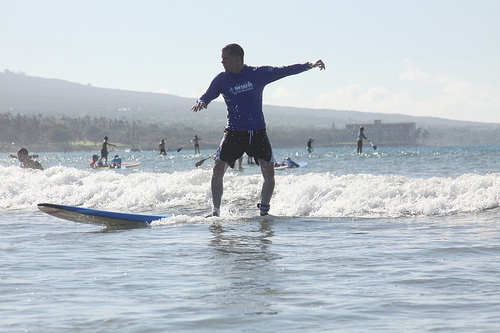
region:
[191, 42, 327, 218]
a man standing on a surfboard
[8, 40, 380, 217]
people playing in the water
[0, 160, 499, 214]
gentle waves in the water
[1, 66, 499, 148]
a hill behind the water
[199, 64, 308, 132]
a blue shirt on the man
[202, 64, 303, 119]
Blue shirt on a man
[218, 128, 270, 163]
Black shorts on a man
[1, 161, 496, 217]
Wave splashing toward a man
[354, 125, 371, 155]
Person in the water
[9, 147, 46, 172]
Person in the water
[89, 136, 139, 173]
People playing in the water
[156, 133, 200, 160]
People in the water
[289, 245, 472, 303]
Ripples in the water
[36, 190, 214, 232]
The blue surfboard is in the water.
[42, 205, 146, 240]
The bottom of the surfboard is white.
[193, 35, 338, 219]
The person is on top of the surfboard.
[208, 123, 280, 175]
The man is wearing a black pant.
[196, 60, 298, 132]
The man is wearing a blue shirt.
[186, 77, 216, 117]
The left arm of the man .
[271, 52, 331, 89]
The right arm of the man.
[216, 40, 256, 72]
The head of the man.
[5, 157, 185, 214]
The white foam on the wave.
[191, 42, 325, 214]
A man with short hair surfing.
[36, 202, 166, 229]
A white and blue surfboard.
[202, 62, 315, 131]
Blue long sleeve shirt on a man surfing.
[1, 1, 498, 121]
A white and blue sky.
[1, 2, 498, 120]
Light blue sky with clouds.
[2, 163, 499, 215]
A small white wave.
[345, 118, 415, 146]
Very large building in the distance.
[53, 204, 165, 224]
Blue edge of a surfboard.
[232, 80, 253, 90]
White mwh on a man's blue shirt front.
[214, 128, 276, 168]
Black and white shorts on a man surfing.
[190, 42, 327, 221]
man on a surfboard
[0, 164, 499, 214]
gentle waves in the water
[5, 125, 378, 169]
people in the background playing in the water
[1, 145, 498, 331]
a large body of water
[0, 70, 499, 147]
green hills behind the water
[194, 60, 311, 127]
blue shirt on the man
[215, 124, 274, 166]
black shorts on the man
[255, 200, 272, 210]
anklet on the man's ankle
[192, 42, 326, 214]
Man in the water surfing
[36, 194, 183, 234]
Long blue surfboard in water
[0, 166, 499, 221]
Large white crashing wave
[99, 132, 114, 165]
Short kid on surfboard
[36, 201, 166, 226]
A blue surfboard coming out of the water.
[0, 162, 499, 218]
A white wave rolling into the shore.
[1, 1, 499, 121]
A blue sky with white clouds.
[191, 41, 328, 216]
A man standing up on a surfboard in a blue shirt and black shorts.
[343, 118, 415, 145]
A large building past the water.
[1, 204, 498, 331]
A blue rippled body of water ahead of the wave.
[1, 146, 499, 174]
A blue body of water behind the wave.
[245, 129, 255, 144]
White tie strings on a black pair of shorts.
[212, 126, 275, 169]
Black and white pair of shorts.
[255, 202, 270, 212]
Black and white ankle strap for a surfboard on a mans left ankle.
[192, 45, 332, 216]
a person is standing up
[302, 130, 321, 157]
a person is standing up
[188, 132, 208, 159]
a person is standing up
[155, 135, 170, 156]
a person is standing up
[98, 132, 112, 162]
a person is standing up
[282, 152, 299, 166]
a person is sitting down